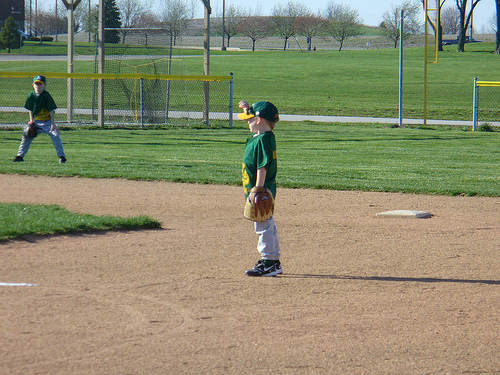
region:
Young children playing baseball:
[0, 62, 487, 363]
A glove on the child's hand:
[242, 182, 282, 231]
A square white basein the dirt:
[375, 200, 435, 224]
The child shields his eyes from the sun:
[230, 95, 259, 121]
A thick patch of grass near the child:
[0, 198, 160, 260]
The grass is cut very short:
[241, 53, 378, 98]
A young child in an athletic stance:
[12, 73, 76, 169]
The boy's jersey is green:
[237, 131, 286, 202]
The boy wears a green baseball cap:
[252, 96, 285, 126]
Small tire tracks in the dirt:
[42, 273, 198, 355]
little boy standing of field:
[234, 91, 297, 277]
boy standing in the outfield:
[14, 73, 73, 163]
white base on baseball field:
[371, 201, 425, 228]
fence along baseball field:
[13, 36, 488, 126]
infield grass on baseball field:
[1, 196, 146, 253]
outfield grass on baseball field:
[6, 115, 499, 190]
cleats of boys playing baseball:
[7, 148, 284, 286]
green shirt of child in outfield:
[22, 93, 54, 124]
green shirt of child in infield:
[237, 130, 279, 189]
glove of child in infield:
[242, 173, 279, 228]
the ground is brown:
[160, 266, 364, 374]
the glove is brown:
[234, 185, 285, 241]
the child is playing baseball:
[220, 98, 307, 300]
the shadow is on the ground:
[292, 259, 499, 315]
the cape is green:
[231, 102, 286, 132]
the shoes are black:
[232, 251, 307, 299]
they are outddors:
[7, 10, 487, 371]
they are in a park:
[5, 8, 493, 374]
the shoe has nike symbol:
[242, 253, 294, 288]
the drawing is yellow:
[30, 104, 57, 129]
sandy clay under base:
[0, 175, 499, 373]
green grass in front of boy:
[1, 200, 162, 254]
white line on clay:
[1, 280, 38, 290]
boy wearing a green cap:
[234, 99, 279, 124]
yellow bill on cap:
[236, 109, 253, 121]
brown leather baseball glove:
[241, 185, 277, 222]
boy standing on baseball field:
[236, 96, 287, 276]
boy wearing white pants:
[253, 221, 278, 258]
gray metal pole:
[396, 9, 408, 124]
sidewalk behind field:
[4, 98, 499, 128]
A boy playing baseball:
[220, 90, 297, 285]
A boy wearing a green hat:
[224, 86, 292, 153]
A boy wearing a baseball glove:
[227, 92, 293, 233]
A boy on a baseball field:
[183, 76, 326, 299]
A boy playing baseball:
[3, 58, 78, 185]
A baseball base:
[334, 151, 464, 268]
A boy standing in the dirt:
[214, 88, 311, 311]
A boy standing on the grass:
[7, 68, 77, 175]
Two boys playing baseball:
[6, 66, 306, 291]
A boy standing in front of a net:
[2, 63, 102, 171]